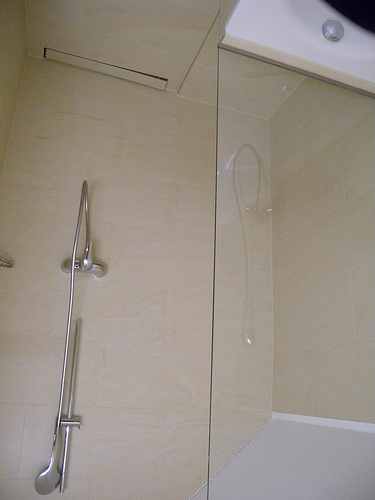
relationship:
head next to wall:
[37, 417, 65, 499] [17, 55, 210, 498]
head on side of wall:
[37, 417, 65, 499] [17, 55, 210, 498]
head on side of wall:
[34, 182, 106, 498] [0, 56, 269, 498]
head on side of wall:
[37, 417, 65, 499] [6, 10, 215, 495]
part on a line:
[234, 397, 344, 464] [188, 416, 274, 498]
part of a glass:
[169, 308, 345, 355] [3, 1, 373, 498]